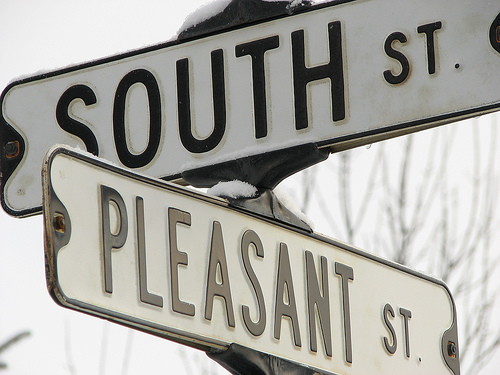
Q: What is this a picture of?
A: Street signs.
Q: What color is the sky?
A: White.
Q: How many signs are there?
A: Two.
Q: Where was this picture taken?
A: South St. and Pleasant St.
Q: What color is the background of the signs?
A: White.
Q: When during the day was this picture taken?
A: Daytime.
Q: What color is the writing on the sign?
A: Black.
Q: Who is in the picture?
A: No one.